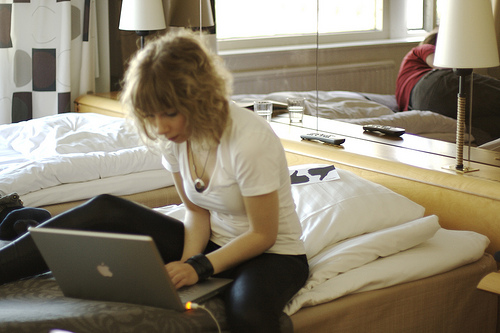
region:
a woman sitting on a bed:
[1, 34, 308, 331]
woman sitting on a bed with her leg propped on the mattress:
[0, 192, 309, 332]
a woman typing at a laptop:
[28, 208, 233, 311]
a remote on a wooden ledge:
[301, 125, 345, 147]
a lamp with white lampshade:
[434, 1, 499, 172]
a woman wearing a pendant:
[185, 125, 220, 194]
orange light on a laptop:
[184, 298, 192, 312]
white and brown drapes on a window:
[1, 0, 110, 122]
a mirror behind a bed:
[110, 0, 497, 167]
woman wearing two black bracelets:
[184, 251, 214, 284]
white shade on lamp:
[428, 27, 497, 78]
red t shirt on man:
[396, 52, 439, 103]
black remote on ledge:
[300, 112, 346, 156]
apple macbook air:
[38, 208, 169, 308]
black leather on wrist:
[180, 234, 222, 291]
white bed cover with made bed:
[36, 125, 116, 170]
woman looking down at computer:
[120, 49, 249, 178]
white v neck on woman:
[161, 158, 332, 240]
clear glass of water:
[266, 90, 308, 136]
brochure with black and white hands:
[299, 138, 348, 194]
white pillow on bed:
[322, 208, 411, 260]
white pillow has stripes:
[306, 195, 343, 237]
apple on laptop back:
[76, 255, 164, 311]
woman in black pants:
[245, 285, 283, 307]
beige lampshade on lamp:
[450, 43, 472, 73]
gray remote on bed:
[311, 128, 388, 160]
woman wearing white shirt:
[263, 175, 277, 180]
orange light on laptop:
[186, 300, 187, 306]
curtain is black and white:
[23, 44, 68, 97]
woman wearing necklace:
[191, 161, 218, 199]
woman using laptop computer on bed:
[0, 29, 494, 331]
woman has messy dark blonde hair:
[119, 26, 231, 154]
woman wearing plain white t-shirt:
[161, 98, 306, 255]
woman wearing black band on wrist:
[184, 253, 217, 283]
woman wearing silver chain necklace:
[185, 133, 212, 190]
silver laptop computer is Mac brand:
[27, 226, 235, 311]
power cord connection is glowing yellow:
[185, 299, 222, 331]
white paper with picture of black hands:
[288, 163, 341, 185]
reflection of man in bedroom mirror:
[393, 30, 498, 140]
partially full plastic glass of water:
[253, 100, 271, 122]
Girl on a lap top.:
[63, 22, 315, 328]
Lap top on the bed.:
[11, 203, 278, 318]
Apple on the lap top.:
[89, 257, 135, 289]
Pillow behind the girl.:
[242, 159, 496, 322]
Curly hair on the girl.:
[118, 33, 265, 142]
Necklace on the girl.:
[173, 130, 223, 215]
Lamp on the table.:
[423, 5, 494, 222]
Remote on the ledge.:
[295, 117, 344, 170]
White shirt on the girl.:
[117, 79, 437, 318]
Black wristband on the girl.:
[178, 241, 240, 290]